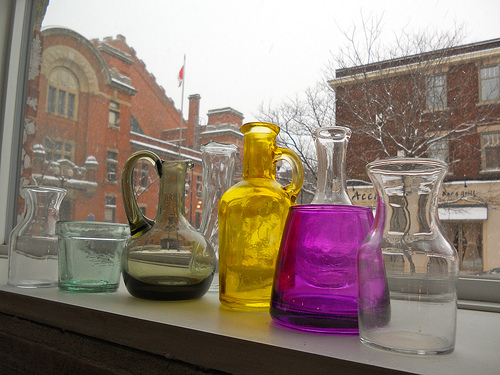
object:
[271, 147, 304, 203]
handle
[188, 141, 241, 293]
bottle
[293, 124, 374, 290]
bottle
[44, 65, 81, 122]
window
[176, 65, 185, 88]
flag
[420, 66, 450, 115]
window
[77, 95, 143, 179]
brick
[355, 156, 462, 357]
vase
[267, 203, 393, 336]
vase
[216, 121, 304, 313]
vase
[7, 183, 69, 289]
vase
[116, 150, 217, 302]
vase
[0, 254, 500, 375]
shelving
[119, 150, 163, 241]
handle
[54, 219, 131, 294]
vase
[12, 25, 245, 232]
building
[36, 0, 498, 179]
sky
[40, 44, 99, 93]
arch